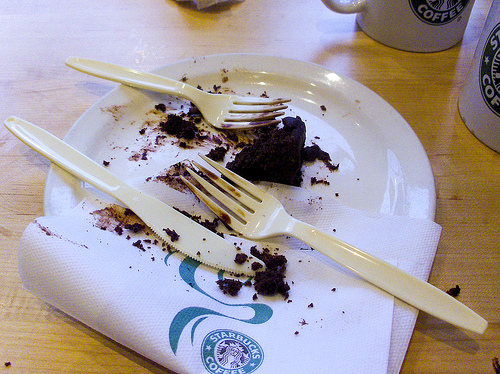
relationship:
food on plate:
[150, 93, 319, 292] [42, 44, 444, 348]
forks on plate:
[59, 50, 426, 261] [42, 44, 444, 348]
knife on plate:
[4, 113, 259, 288] [42, 44, 444, 348]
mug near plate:
[314, 2, 499, 152] [42, 44, 444, 348]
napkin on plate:
[20, 214, 421, 370] [42, 44, 444, 348]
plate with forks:
[42, 44, 444, 348] [59, 50, 426, 261]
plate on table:
[42, 44, 444, 348] [2, 2, 497, 372]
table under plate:
[2, 2, 497, 372] [42, 44, 444, 348]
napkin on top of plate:
[20, 214, 421, 370] [42, 44, 444, 348]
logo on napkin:
[195, 317, 270, 372] [20, 214, 421, 370]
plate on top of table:
[42, 44, 444, 348] [2, 2, 497, 372]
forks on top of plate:
[59, 50, 426, 261] [42, 44, 444, 348]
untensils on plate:
[2, 2, 497, 372] [42, 44, 444, 348]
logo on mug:
[195, 317, 270, 372] [314, 2, 499, 152]